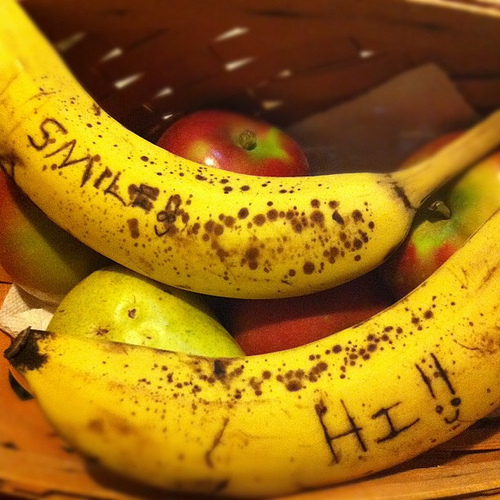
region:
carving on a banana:
[292, 342, 474, 469]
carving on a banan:
[29, 108, 200, 233]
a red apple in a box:
[147, 73, 322, 190]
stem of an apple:
[234, 123, 266, 155]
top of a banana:
[5, 315, 72, 415]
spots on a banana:
[175, 255, 461, 397]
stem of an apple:
[386, 193, 474, 228]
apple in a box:
[221, 280, 403, 361]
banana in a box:
[10, 54, 496, 288]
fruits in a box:
[40, 53, 497, 491]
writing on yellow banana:
[310, 382, 420, 469]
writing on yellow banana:
[19, 105, 224, 268]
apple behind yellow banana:
[142, 91, 310, 240]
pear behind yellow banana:
[36, 253, 254, 390]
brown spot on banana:
[236, 208, 271, 239]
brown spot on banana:
[204, 211, 233, 246]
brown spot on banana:
[323, 339, 365, 371]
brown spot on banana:
[282, 365, 316, 406]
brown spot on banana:
[244, 369, 275, 394]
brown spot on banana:
[194, 365, 234, 397]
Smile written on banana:
[26, 113, 157, 214]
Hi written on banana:
[305, 391, 420, 466]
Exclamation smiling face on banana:
[414, 348, 473, 427]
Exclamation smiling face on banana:
[149, 193, 186, 244]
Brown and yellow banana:
[3, 205, 498, 497]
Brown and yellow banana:
[0, 0, 499, 300]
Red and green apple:
[157, 107, 311, 176]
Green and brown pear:
[33, 265, 245, 362]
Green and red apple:
[388, 123, 498, 295]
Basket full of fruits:
[3, 7, 498, 494]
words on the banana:
[23, 114, 198, 241]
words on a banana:
[293, 349, 472, 454]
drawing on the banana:
[411, 345, 472, 427]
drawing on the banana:
[148, 189, 183, 239]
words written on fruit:
[309, 394, 420, 459]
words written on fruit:
[26, 112, 158, 217]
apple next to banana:
[160, 101, 312, 178]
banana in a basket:
[3, 0, 413, 307]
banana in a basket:
[0, 217, 497, 491]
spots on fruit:
[225, 204, 375, 266]